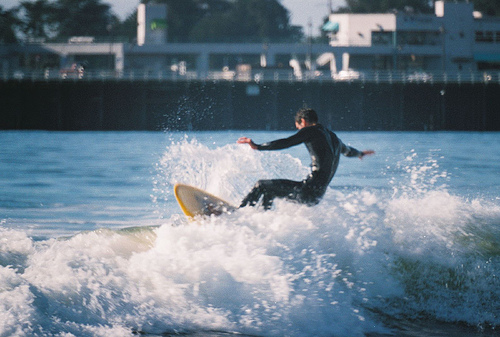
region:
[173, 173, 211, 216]
a surfboard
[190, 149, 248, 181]
a splash of water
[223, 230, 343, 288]
the water is white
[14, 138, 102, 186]
the water is blue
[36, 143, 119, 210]
the oceans water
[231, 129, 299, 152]
the surfer has his hand out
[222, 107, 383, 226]
the person is surfing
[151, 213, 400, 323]
a big wave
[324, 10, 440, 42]
a building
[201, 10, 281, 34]
a green bush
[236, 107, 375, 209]
A man in a black wetsuit surfing.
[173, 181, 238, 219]
The white tip of a surfboard with orange trim.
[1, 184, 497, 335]
A large white wave.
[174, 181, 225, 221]
Yellow trim on a white surfboard.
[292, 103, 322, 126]
The black hair of a man surfing.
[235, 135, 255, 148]
A man's left hand.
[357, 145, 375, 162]
Right hand of a man surfing.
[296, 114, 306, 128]
A left ear on a surfer.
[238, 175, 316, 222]
Black legs on a man.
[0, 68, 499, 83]
A white railing above a black wall.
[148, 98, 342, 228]
person surfing in blue ocean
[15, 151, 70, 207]
blue and white ocean waves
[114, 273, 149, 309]
blue and white ocean waves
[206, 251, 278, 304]
blue and white ocean waves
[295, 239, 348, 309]
blue and white ocean waves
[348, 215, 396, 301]
blue and white ocean waves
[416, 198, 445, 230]
blue and white ocean waves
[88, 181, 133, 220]
blue and white ocean waves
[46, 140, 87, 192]
blue and white ocean waves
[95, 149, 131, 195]
blue and white ocean waves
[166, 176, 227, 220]
A white surfboard with yellow trim.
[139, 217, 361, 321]
Waves rising up out of the water.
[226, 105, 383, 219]
The surfer is wearing a black wetsuit.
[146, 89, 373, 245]
This is a surfer riding a wave.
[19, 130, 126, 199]
The water here is blue and calm.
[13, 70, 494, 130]
A large black enclosure.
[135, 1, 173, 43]
A large tower in the distance.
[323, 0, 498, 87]
A large white building.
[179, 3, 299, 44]
Trees growing near the building.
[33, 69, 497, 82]
Barbed wire atop the wall.